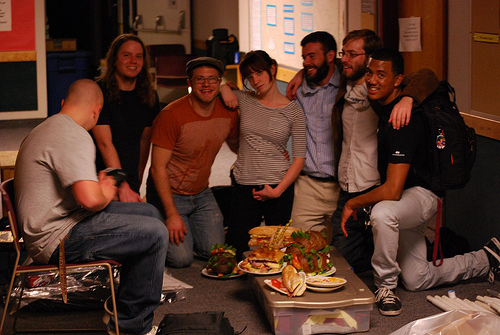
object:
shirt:
[88, 74, 160, 194]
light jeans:
[369, 185, 490, 292]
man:
[341, 51, 499, 317]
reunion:
[0, 21, 499, 335]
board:
[0, 0, 48, 119]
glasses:
[186, 76, 222, 85]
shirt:
[148, 94, 239, 196]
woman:
[87, 34, 161, 197]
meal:
[202, 224, 346, 296]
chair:
[1, 175, 120, 335]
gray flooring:
[84, 267, 499, 335]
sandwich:
[239, 248, 285, 274]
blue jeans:
[161, 187, 226, 269]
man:
[150, 56, 291, 268]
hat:
[185, 56, 225, 72]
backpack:
[406, 79, 487, 189]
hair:
[94, 32, 155, 106]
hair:
[239, 49, 279, 91]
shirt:
[227, 90, 306, 186]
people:
[13, 79, 169, 335]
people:
[88, 34, 162, 203]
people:
[218, 50, 308, 261]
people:
[289, 31, 346, 231]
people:
[284, 28, 468, 283]